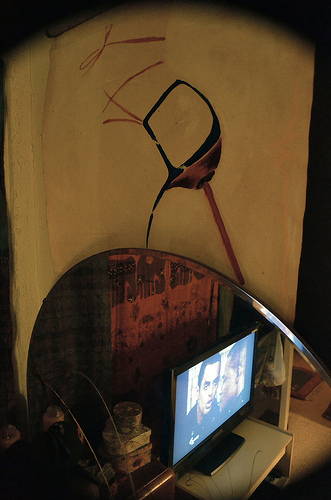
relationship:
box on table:
[98, 402, 152, 476] [22, 433, 190, 494]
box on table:
[99, 418, 151, 455] [114, 462, 176, 499]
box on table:
[98, 402, 152, 476] [114, 462, 176, 499]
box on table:
[98, 402, 152, 476] [43, 422, 178, 497]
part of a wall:
[40, 206, 129, 242] [48, 151, 130, 228]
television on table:
[166, 322, 259, 483] [177, 412, 293, 499]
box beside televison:
[98, 402, 152, 476] [78, 370, 182, 489]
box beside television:
[98, 402, 152, 476] [157, 322, 262, 472]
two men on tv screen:
[177, 340, 246, 446] [159, 319, 262, 480]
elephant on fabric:
[135, 250, 164, 298] [29, 251, 225, 422]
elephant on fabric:
[73, 254, 205, 308] [29, 251, 225, 422]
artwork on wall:
[14, 8, 313, 399] [0, 0, 330, 414]